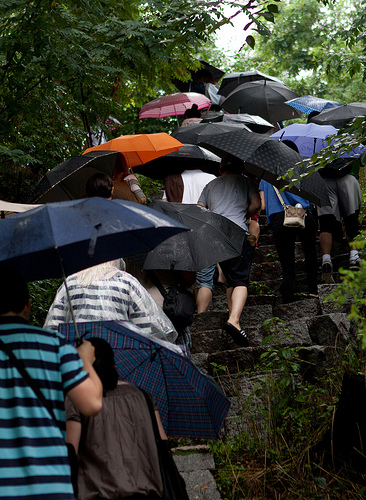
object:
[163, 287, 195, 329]
bag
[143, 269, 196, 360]
person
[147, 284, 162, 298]
shoulder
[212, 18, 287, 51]
rain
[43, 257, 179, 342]
coat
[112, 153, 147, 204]
people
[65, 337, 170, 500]
people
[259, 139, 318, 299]
people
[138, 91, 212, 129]
umbrellas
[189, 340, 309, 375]
step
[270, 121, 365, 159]
blue umbrella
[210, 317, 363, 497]
grass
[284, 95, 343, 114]
umbrella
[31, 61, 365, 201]
wet umbrellas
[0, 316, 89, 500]
black shirt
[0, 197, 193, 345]
umbrella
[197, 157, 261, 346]
man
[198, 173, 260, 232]
shirt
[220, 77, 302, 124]
umbrella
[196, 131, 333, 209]
umbrella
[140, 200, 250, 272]
umbrella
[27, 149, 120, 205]
umbrella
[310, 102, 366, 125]
umbrella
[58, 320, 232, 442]
umbrella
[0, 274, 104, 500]
man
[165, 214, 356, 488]
stairs